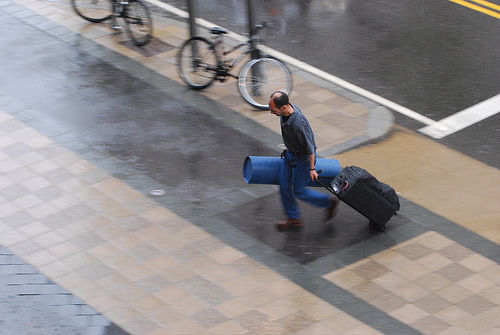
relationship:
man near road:
[254, 89, 341, 237] [151, 4, 497, 139]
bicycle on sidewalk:
[174, 20, 296, 110] [0, 0, 498, 331]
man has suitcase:
[254, 89, 341, 237] [318, 166, 404, 229]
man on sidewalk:
[254, 89, 341, 237] [0, 0, 498, 331]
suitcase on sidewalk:
[318, 166, 404, 229] [0, 0, 498, 331]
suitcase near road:
[318, 166, 404, 229] [151, 4, 497, 139]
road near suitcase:
[151, 4, 497, 139] [318, 166, 404, 229]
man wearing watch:
[266, 89, 341, 232] [306, 169, 321, 180]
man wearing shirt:
[266, 89, 341, 232] [275, 104, 318, 172]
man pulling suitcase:
[266, 89, 341, 232] [333, 164, 403, 224]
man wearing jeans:
[266, 89, 341, 232] [275, 152, 337, 236]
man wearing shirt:
[266, 89, 341, 232] [270, 110, 319, 166]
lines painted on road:
[145, 0, 498, 144] [151, 4, 497, 139]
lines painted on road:
[434, 0, 498, 21] [151, 4, 497, 139]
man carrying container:
[266, 89, 341, 232] [239, 152, 350, 185]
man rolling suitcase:
[254, 89, 341, 237] [333, 164, 403, 224]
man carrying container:
[254, 89, 341, 237] [242, 155, 341, 187]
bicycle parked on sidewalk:
[176, 20, 295, 110] [0, 0, 498, 331]